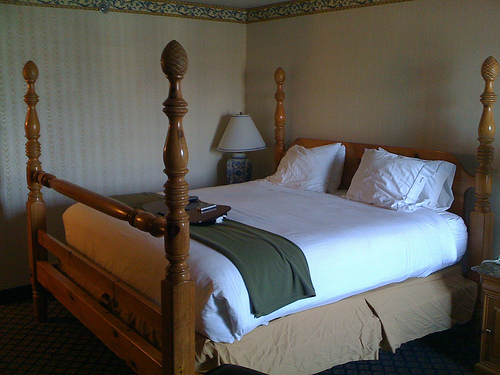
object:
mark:
[103, 293, 120, 313]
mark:
[63, 289, 75, 304]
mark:
[168, 220, 179, 238]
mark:
[58, 245, 78, 256]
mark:
[127, 355, 137, 369]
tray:
[143, 186, 231, 227]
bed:
[23, 69, 494, 374]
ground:
[401, 189, 423, 208]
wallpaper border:
[0, 0, 408, 23]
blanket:
[112, 185, 317, 318]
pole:
[35, 166, 165, 240]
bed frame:
[21, 39, 499, 374]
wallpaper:
[104, 2, 346, 16]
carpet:
[314, 324, 480, 374]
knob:
[481, 325, 498, 341]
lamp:
[212, 107, 267, 184]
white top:
[211, 109, 270, 155]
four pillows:
[263, 143, 456, 215]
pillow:
[342, 146, 433, 213]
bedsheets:
[60, 264, 481, 374]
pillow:
[265, 138, 342, 192]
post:
[156, 38, 190, 81]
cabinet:
[35, 238, 164, 352]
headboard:
[287, 137, 477, 215]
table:
[473, 258, 499, 372]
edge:
[469, 258, 488, 367]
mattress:
[61, 161, 469, 343]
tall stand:
[159, 37, 196, 372]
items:
[196, 200, 217, 212]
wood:
[21, 38, 497, 374]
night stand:
[468, 255, 498, 372]